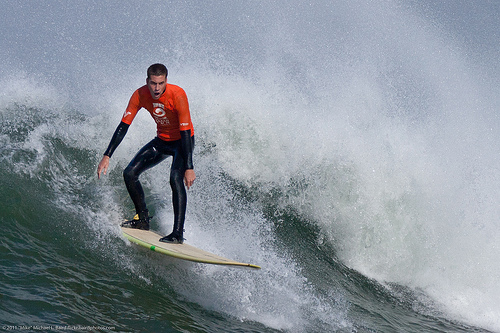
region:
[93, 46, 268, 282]
man on a surfboard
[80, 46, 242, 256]
man wearing a red t-shirt on a surfboard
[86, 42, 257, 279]
man wearing a black body suit on a surfboard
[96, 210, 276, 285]
tan and green surfboard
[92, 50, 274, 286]
man riding on a surfboard in the ocean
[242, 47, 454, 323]
ocean wave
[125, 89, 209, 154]
red and white t-shirt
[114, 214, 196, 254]
black surf shoes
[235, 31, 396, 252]
white ocean wave mist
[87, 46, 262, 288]
man standing on a surfboard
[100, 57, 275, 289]
A man surfing in the ocean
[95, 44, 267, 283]
A male surfer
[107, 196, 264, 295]
A white surfing board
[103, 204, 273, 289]
A white surfboard in the water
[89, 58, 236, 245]
A male surfer that is wet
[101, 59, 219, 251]
A wet man in the ocean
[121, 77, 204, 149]
An orange shirt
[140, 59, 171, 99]
The head of a surfer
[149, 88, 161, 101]
The open mouth of a surfer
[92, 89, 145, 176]
The right arm of the surfer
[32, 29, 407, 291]
this guy is riding the waves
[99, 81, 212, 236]
he has on an orange and black wet suit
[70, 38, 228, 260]
he is standing on his skateboard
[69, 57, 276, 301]
he makes surfing look easy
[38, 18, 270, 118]
the water is spraying behind the man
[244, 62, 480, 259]
this wave looks rough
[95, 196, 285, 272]
he is wearing black surf shoes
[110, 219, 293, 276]
his skateboard is tan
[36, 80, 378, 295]
this wave is wild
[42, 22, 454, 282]
the water looks rough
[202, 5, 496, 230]
ocean spray off the wave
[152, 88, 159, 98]
wide open mouth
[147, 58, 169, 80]
short brown hair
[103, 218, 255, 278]
beige and green surf board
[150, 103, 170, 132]
white printed logo on shirt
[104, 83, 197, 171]
long sleeved black orange and white wetsuit shirt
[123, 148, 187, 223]
black long legged wet suit pants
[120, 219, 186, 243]
black swimmer shoes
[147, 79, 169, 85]
black bushy eye brows of surfer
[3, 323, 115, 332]
white lettering of photo credits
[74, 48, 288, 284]
man on a surfboard on a wave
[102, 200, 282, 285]
surfboard on a wave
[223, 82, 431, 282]
spray from an ocean wave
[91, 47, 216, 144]
mans face with orange shirt on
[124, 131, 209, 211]
black surfing wet suit pants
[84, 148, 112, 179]
surfer's right hand on arm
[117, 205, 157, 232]
right foot of the surfer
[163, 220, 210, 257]
left foot of the surfer